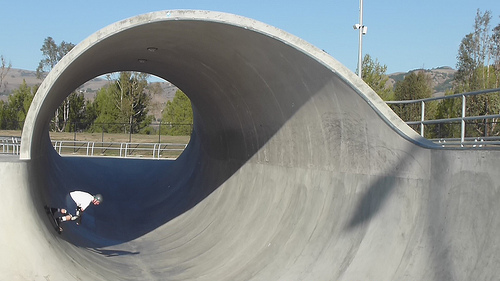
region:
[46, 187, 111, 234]
person inside of skate ramp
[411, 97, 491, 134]
gray railing by skate ramp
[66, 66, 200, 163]
opening of the skate ramp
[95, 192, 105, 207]
the person's head in ramp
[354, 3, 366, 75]
lights on gray pole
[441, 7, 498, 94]
tree limbs and branches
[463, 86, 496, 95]
silver metal fence pole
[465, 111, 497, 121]
silver metal fence pole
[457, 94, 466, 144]
silver metal fence pole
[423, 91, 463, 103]
silver metal fence pole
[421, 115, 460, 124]
silver metal fence pole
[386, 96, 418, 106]
silver metal fence pole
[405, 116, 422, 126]
silver metal fence pole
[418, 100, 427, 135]
silver metal fence pole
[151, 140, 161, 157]
silver metal fence pole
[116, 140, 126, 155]
silver metal fence pole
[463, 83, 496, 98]
metal pole on fence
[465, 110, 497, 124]
metal pole on fence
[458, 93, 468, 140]
metal pole on fence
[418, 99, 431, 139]
metal pole on fence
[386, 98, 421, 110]
metal pole on fence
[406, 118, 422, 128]
metal pole on fence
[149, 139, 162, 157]
metal pole on fence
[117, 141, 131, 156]
metal pole on fence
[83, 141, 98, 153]
metal pole on fence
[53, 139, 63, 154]
metal pole on fence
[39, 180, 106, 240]
person skateboarding around skate rampp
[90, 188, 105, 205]
helmet on skateboarder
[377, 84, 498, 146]
metal fence surrouding skateboard cylinder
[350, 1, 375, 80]
street light on pole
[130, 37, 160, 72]
lights on top of stone skate ramp tunnel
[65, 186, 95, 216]
white short sleeve t-shirt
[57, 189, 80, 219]
pair of black shorts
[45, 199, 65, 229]
pair of black shoes with white soles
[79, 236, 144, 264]
shadow of skateboarder on stone skateboard ramp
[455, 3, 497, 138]
tall tree behind fence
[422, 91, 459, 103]
metal pole on fence